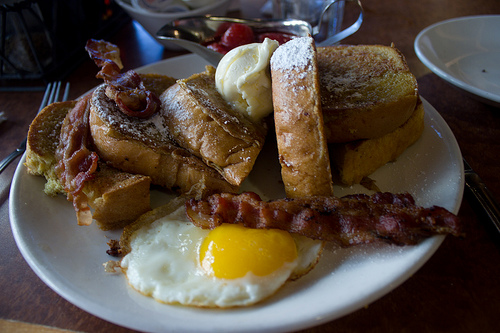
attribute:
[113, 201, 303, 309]
eggs — close, white, yellow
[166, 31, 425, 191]
bread — white, brown, toasted, golden brown, french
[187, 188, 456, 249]
bacon — crisp, red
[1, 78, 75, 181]
fork — silver, small, grey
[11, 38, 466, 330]
plate — full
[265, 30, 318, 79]
sugar — powdered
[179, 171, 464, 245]
bacon — greasy 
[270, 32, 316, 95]
sugar — powdered, top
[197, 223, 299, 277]
yolk — yellow